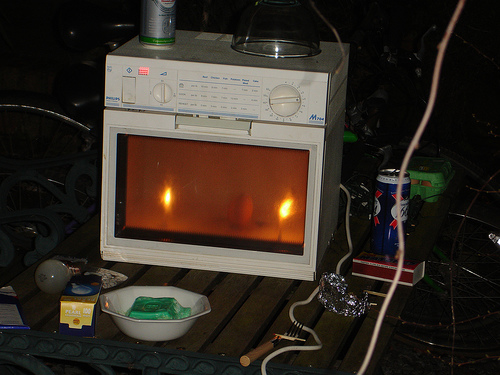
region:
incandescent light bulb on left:
[35, 255, 79, 294]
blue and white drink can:
[367, 163, 409, 279]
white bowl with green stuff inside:
[100, 285, 217, 345]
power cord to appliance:
[266, 67, 446, 374]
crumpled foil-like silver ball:
[317, 269, 374, 324]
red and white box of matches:
[348, 258, 425, 290]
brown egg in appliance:
[223, 188, 260, 236]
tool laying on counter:
[231, 328, 308, 373]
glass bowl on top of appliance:
[231, 15, 328, 62]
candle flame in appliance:
[268, 194, 300, 243]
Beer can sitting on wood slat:
[371, 172, 406, 252]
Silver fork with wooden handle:
[242, 316, 301, 358]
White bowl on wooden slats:
[104, 287, 214, 333]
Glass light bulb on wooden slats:
[32, 260, 79, 292]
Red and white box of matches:
[355, 252, 427, 287]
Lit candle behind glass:
[276, 196, 292, 248]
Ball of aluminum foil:
[327, 273, 370, 315]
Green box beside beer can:
[412, 154, 452, 200]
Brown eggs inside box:
[410, 174, 430, 186]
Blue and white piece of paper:
[3, 287, 25, 331]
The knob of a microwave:
[261, 82, 306, 115]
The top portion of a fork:
[277, 320, 307, 336]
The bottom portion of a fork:
[230, 337, 276, 367]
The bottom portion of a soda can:
[375, 181, 408, 257]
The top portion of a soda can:
[371, 163, 411, 184]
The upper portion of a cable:
[390, 1, 477, 158]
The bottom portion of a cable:
[330, 208, 422, 372]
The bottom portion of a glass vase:
[228, 36, 328, 57]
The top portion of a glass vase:
[225, 0, 330, 37]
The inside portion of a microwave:
[110, 136, 310, 253]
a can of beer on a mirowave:
[136, 1, 178, 47]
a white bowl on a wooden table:
[100, 281, 210, 341]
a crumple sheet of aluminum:
[317, 271, 370, 320]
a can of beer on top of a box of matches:
[374, 165, 410, 265]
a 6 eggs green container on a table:
[408, 153, 457, 204]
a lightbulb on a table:
[36, 255, 82, 294]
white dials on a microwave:
[151, 80, 303, 116]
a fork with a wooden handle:
[240, 317, 305, 372]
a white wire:
[264, 1, 468, 373]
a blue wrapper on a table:
[0, 284, 29, 331]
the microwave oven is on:
[62, 2, 395, 288]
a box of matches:
[343, 242, 432, 305]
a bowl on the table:
[90, 267, 214, 347]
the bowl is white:
[92, 252, 223, 342]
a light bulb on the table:
[22, 249, 89, 292]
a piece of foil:
[290, 253, 391, 330]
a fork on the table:
[227, 310, 319, 365]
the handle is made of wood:
[222, 328, 279, 366]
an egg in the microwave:
[178, 169, 293, 245]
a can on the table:
[354, 160, 424, 252]